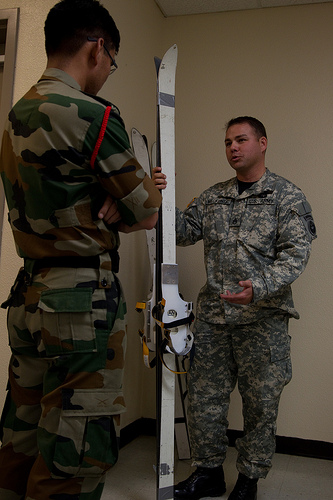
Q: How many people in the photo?
A: Two.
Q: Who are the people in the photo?
A: Military men.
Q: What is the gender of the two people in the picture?
A: Male.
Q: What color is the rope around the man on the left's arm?
A: Red.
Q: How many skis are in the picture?
A: Two.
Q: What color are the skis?
A: White.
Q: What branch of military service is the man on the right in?
A: U.S. Army.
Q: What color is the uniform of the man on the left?
A: Green and brown.